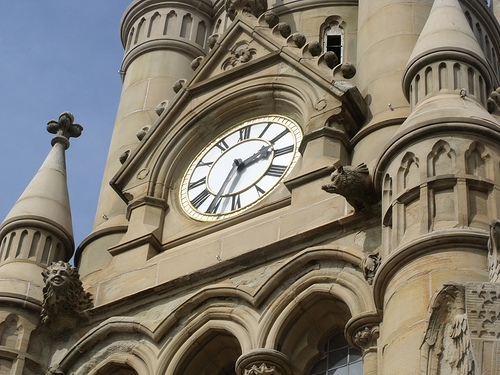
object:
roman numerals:
[230, 193, 243, 209]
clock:
[179, 114, 303, 221]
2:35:
[186, 123, 297, 213]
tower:
[0, 0, 499, 375]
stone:
[0, 0, 499, 374]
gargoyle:
[322, 162, 376, 211]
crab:
[220, 40, 256, 71]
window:
[325, 35, 341, 59]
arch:
[255, 246, 380, 375]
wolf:
[322, 161, 379, 215]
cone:
[1, 142, 76, 263]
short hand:
[234, 143, 274, 169]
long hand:
[205, 159, 241, 212]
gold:
[177, 112, 303, 222]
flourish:
[353, 326, 379, 356]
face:
[47, 265, 70, 286]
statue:
[39, 260, 92, 335]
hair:
[39, 260, 95, 329]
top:
[46, 111, 85, 153]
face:
[179, 116, 304, 222]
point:
[268, 141, 276, 152]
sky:
[0, 1, 135, 267]